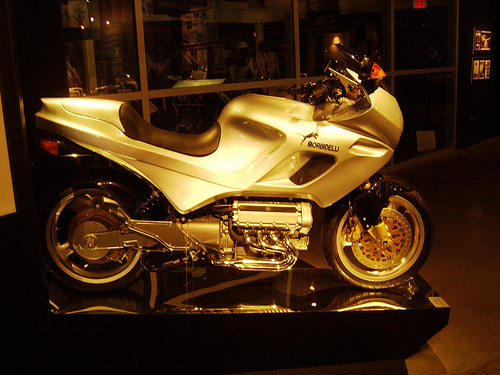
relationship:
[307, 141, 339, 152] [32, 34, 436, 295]
logo on bike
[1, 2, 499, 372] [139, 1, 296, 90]
building has window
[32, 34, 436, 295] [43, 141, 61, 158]
bike has a light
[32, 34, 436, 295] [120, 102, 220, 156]
bike has a seat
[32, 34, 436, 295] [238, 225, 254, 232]
bike has a cyclinder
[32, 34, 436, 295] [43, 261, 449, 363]
bike on a platform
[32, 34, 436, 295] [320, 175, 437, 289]
bike has a tire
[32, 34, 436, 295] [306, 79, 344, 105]
bike has a handlebar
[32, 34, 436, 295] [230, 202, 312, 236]
bike has an engine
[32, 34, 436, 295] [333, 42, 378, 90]
bike has a window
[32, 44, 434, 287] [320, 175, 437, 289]
bike has a tire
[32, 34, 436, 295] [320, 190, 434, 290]
bike has a tire